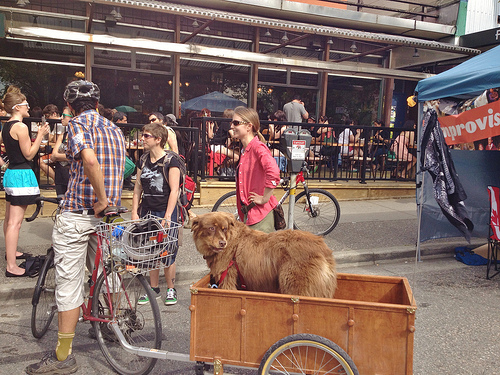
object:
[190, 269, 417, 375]
wagon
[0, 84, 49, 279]
person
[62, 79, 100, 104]
helmet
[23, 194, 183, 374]
bicycle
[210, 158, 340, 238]
bicycle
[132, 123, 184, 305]
person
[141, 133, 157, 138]
sunglasses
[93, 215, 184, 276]
basket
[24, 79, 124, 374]
cyclist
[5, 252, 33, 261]
flats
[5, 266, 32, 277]
flats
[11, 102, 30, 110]
sunglasses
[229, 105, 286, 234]
person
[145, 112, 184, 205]
person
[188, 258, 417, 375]
cart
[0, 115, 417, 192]
metal fence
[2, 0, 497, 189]
restaurant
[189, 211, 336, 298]
dog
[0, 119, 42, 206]
dress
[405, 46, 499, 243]
blue tent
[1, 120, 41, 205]
outfit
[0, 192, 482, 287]
sidewalk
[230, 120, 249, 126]
sunglasses